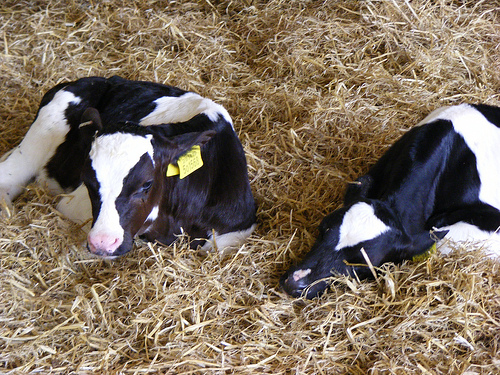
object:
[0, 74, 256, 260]
calf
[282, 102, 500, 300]
calf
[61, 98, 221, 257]
head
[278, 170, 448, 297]
head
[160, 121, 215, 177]
ear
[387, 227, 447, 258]
ear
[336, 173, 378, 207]
ear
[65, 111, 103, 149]
ear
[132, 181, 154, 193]
eye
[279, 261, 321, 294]
nose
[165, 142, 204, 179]
paper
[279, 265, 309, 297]
nose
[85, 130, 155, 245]
line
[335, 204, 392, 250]
diamond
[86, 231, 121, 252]
nose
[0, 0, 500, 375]
ground